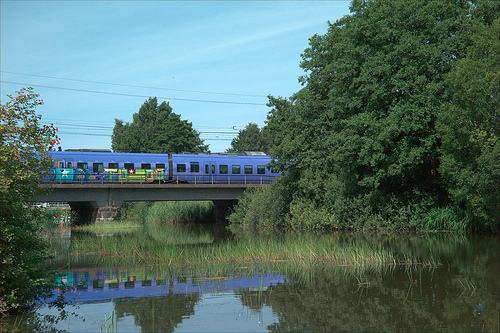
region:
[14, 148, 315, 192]
a blue train over the water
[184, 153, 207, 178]
a window on the train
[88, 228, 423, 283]
grass in the water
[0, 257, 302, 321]
a reflection in the water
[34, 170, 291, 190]
a small guard rail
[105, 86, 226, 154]
a leafy green tree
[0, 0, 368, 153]
a clear blue sky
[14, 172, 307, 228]
a cement bridge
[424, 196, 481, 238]
a patch of grass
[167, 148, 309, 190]
a train car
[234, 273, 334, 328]
The water is visible.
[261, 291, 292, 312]
The water is visible.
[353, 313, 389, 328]
The water is visible.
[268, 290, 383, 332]
The water is visible.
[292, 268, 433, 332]
The water is visible.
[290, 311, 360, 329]
The water is visible.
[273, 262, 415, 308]
The water is visible.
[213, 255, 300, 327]
The water is visible.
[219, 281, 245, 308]
The water is visible.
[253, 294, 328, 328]
The water is visible.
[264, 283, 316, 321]
The water is visible.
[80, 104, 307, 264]
train on a bridge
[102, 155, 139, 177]
windows on train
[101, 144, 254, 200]
two parts of the train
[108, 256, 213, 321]
reflection of the train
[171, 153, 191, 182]
square window of train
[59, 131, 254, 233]
long and blue train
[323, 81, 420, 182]
green tree next to water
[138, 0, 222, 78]
blue sky above land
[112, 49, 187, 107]
white clouds in sky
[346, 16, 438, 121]
green leaves on tree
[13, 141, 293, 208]
blue train on a bridge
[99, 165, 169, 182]
design on the bridge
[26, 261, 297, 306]
reflection of the train in the water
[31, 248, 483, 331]
tiny brown pond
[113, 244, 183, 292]
grass growing out of the water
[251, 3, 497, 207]
thick green tree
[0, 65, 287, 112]
two black wires running parallel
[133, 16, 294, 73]
streaks of white clouds in the blue sky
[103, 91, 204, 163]
tree top poking over the top of the train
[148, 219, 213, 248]
reflection of the tree in the water